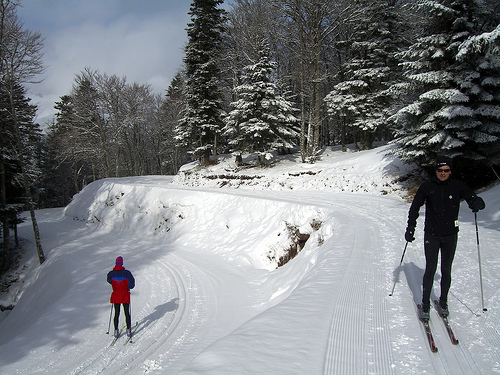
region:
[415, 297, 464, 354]
Man on skis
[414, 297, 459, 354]
Man is on skis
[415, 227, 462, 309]
Man wearing pants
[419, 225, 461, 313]
Man is wearing pants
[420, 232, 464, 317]
Man wearing black pants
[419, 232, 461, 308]
Man is wearing black pants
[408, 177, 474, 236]
Man wearing a jacket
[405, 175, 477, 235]
Man is wearing a jacket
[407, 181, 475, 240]
Man wearing a black jacket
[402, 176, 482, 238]
Man is wearing a black jacket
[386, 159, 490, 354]
man wearing black boots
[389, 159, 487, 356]
man wearing black pants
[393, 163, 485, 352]
man wearing black gloves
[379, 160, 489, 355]
man wearing black jacket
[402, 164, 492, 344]
man wearing black hat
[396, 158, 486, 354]
man wearing black glasses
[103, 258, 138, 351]
man wearing black pants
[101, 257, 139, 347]
man wearing red coat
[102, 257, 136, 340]
man wearing red hat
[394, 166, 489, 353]
man holding ski poles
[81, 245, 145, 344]
A man snow sketing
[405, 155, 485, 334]
A man snow sketing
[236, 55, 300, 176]
A green tree covered by snow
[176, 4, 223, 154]
A green tree covered by snow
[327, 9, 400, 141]
A green tree covered by snow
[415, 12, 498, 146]
A green tree covered by snow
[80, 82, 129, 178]
A leafless tall tree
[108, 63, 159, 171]
A leafless tall tree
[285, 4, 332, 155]
A leafless tall tree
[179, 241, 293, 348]
A white field of snow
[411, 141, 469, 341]
person skiing on mountain side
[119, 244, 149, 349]
person skiing on mountain side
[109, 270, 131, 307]
red jacket on skier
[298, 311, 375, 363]
thick white snow on mountain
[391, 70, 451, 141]
snow covering branches of trees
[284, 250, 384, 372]
snowmobile marks in snow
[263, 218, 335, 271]
rocks sticking out of snow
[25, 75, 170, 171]
brown trees around skiers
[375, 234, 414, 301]
ski pole in skier's hand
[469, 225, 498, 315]
ski pole in skier's hand